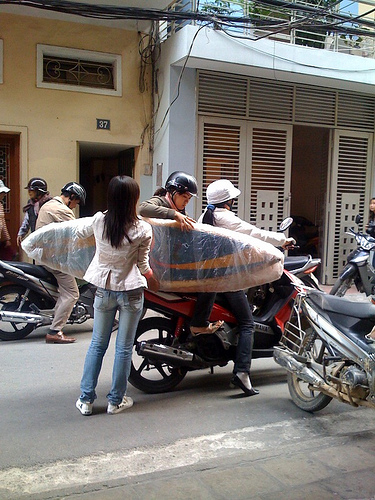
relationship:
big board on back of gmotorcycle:
[21, 213, 283, 293] [125, 216, 306, 393]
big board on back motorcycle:
[21, 213, 283, 293] [113, 288, 362, 358]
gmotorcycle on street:
[125, 216, 306, 393] [1, 307, 373, 499]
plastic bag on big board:
[27, 224, 94, 269] [21, 213, 283, 293]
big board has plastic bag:
[21, 213, 283, 293] [27, 224, 94, 269]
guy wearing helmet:
[35, 181, 86, 344] [61, 177, 91, 202]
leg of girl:
[103, 306, 144, 417] [138, 170, 224, 338]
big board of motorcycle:
[21, 213, 283, 293] [125, 187, 341, 446]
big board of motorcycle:
[21, 213, 283, 293] [123, 217, 324, 391]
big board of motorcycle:
[21, 213, 283, 293] [13, 153, 336, 415]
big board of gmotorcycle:
[21, 213, 283, 293] [125, 262, 311, 385]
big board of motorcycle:
[21, 213, 283, 293] [93, 250, 328, 406]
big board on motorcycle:
[21, 213, 283, 293] [123, 217, 324, 391]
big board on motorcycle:
[21, 213, 283, 293] [139, 253, 316, 411]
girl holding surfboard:
[69, 174, 161, 418] [11, 206, 285, 306]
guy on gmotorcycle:
[35, 181, 86, 343] [0, 259, 96, 341]